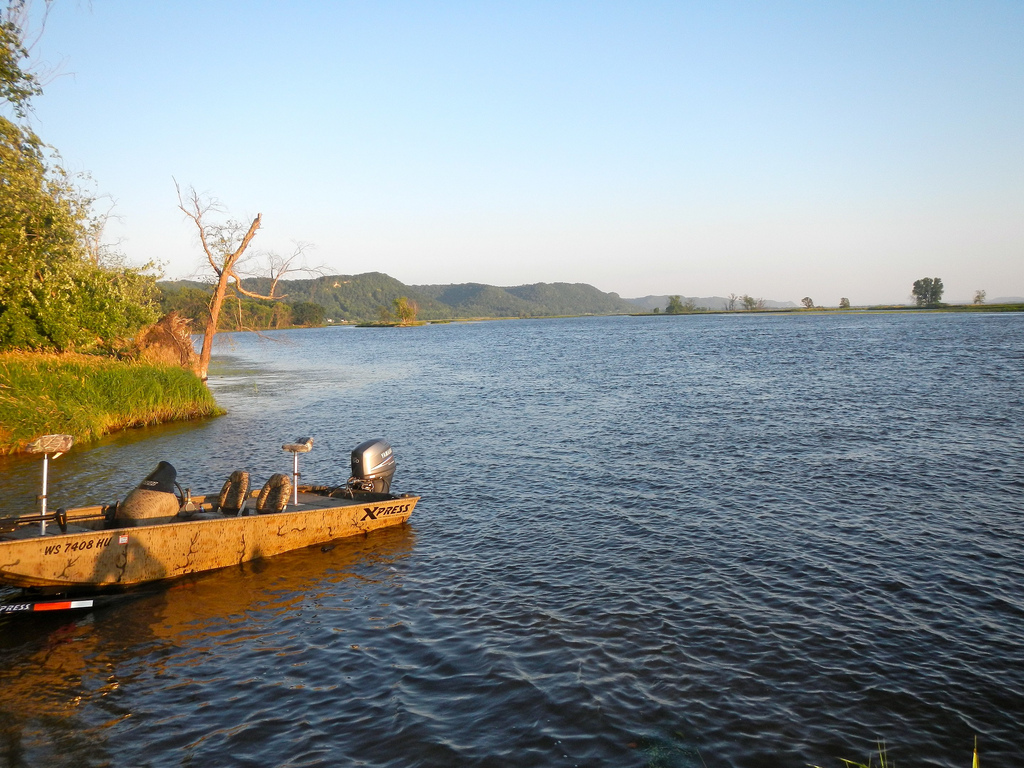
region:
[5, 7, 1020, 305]
A light blue sky.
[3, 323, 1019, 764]
A blue rippled body of water.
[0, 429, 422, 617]
A small fishing boat.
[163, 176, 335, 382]
A leafless tree angled over the water.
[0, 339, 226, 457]
A green grassy bank of land past a boat.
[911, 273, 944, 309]
Largest tree across the water.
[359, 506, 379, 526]
Large black X in Xpress.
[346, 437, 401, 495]
Black motor on a boat.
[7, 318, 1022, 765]
A blue body of water.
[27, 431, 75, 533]
Tallest pole and seat on a boat.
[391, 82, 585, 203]
a view of sky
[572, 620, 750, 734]
a view of water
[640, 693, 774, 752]
riddle on the water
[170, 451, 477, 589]
a view of boat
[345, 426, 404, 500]
a view of box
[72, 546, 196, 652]
a view of shadow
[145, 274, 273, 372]
a view of trees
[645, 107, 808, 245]
a view of clouds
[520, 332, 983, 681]
water has many ripples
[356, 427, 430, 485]
engine on boat is silver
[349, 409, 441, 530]
boat has an engine on it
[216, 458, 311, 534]
boat has two seats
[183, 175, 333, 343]
tree has no leaves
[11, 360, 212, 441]
the grass is very long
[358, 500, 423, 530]
the letters on the boat are black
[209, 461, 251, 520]
seat in the boat on the water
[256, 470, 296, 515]
seat in the boat on the water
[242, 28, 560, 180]
a sky that is blue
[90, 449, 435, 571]
a boat that is brown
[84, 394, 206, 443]
some grass that is yellow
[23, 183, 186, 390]
a bush that is green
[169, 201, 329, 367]
a tree that is without leaves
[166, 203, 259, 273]
some branches on a tree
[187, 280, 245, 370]
a trunk that is on a tree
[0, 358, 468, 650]
a boat in the water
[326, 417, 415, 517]
engine for a speedboat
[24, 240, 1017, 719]
a body of water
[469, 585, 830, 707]
small ripples in the water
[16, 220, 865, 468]
shore line along a body of water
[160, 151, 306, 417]
dead tree on the edge of the water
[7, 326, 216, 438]
green grasses next to water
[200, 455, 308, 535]
seats on a boat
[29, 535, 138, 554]
serial number on a boat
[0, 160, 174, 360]
a section of trees by the water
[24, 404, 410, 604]
Boat on the water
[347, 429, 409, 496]
black engine on the boat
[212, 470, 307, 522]
two seats on the boat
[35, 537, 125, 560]
black writing on the boat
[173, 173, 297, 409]
Tree on the shore line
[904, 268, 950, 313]
Tree on the shore line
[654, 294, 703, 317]
Tree on the shore line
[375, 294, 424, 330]
Tree on the shore line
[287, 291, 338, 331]
Tree on the shore line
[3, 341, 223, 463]
grass growing on the shoreline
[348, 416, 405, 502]
motor on the boat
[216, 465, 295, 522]
seats on the boat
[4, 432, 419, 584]
boat next to the land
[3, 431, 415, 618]
A small wooden boat.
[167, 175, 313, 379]
A leafless tree.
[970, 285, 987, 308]
A tree in the distance.